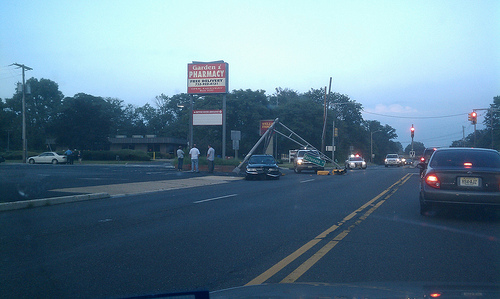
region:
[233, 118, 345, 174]
street sign that has fallen into the road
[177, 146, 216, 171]
people standing next to the fallen sign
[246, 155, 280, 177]
car that hit the post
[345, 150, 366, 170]
police car in the intersection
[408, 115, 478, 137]
two red traffic lights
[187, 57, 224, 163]
red and white pharmacy sign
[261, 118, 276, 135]
red and yellow Wells Fargo sign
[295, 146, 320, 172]
truck behind the fallen street sign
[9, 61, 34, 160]
telephone pole with transformers on the left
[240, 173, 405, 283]
yellow double line in the street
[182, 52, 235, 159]
two red and white signs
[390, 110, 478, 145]
two traffic lights with red lights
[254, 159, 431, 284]
yellow double lines painted on highway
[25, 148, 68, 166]
white car in parking lot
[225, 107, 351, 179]
structure holding signs that has fallen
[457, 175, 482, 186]
license plate of gray car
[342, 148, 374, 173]
police car with lights on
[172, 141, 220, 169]
three standing near sign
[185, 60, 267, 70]
white text on red sign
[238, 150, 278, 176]
car that pole has fallen on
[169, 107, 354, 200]
An accident happen on the street.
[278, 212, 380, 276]
Two yellow lines in the street.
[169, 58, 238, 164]
A sign in the parking lot.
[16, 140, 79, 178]
A car parked on the side of road.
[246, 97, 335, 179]
A pole fell on top of a car.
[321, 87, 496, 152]
The traffic light is red.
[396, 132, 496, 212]
Cars riding down the street.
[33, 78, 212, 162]
Trees behind the house.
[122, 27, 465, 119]
The sky is blue and clear.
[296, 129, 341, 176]
A greeen sign on the ground.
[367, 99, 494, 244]
Cars on a street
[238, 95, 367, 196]
An accident scene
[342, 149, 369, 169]
A police car with its lights on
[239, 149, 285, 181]
A car that hit a pole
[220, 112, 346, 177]
A pole that has fallen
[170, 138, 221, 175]
Three men standing in a parking lot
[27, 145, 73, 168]
A car in a parking lot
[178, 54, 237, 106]
A red and white sign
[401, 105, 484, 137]
Two stop lights on the street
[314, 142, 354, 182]
Stop lights on the ground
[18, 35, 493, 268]
street and parking lot in town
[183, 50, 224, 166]
metal poles elevating red and white signs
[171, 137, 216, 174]
men standing on paved surface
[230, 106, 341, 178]
dented car under fallen street pole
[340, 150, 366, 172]
police car with red and white lights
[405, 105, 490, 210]
red traffic lights by cars with red rear lights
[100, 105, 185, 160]
low brown building under trees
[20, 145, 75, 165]
white car with people at rear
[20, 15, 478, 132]
bright light-blue sky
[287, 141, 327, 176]
vehicle with white light behind sign